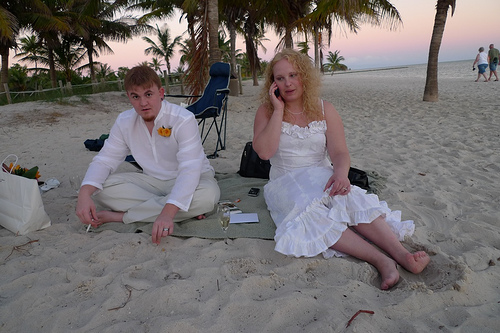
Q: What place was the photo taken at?
A: It was taken at the beach.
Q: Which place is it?
A: It is a beach.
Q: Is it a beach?
A: Yes, it is a beach.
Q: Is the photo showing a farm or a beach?
A: It is showing a beach.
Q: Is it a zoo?
A: No, it is a beach.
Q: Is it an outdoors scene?
A: Yes, it is outdoors.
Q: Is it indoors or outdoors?
A: It is outdoors.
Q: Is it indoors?
A: No, it is outdoors.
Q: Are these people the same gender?
A: No, they are both male and female.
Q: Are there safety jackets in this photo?
A: No, there are no safety jackets.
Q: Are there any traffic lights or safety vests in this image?
A: No, there are no safety vests or traffic lights.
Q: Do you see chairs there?
A: Yes, there is a chair.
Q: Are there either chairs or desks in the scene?
A: Yes, there is a chair.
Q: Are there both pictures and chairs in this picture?
A: No, there is a chair but no pictures.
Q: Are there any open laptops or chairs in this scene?
A: Yes, there is an open chair.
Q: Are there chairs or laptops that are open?
A: Yes, the chair is open.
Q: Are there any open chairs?
A: Yes, there is an open chair.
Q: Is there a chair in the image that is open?
A: Yes, there is a chair that is open.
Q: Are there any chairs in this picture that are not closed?
A: Yes, there is a open chair.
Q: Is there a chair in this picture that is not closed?
A: Yes, there is a open chair.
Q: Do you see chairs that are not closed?
A: Yes, there is a open chair.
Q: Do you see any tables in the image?
A: No, there are no tables.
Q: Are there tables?
A: No, there are no tables.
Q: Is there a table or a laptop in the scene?
A: No, there are no tables or laptops.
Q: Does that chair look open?
A: Yes, the chair is open.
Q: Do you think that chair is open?
A: Yes, the chair is open.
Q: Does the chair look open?
A: Yes, the chair is open.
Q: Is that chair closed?
A: No, the chair is open.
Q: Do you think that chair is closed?
A: No, the chair is open.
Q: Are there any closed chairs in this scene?
A: No, there is a chair but it is open.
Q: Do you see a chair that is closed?
A: No, there is a chair but it is open.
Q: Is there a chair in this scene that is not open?
A: No, there is a chair but it is open.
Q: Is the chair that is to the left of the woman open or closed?
A: The chair is open.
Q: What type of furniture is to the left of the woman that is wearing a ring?
A: The piece of furniture is a chair.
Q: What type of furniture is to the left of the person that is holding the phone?
A: The piece of furniture is a chair.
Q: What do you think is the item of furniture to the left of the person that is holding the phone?
A: The piece of furniture is a chair.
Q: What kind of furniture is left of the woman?
A: The piece of furniture is a chair.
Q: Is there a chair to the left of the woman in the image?
A: Yes, there is a chair to the left of the woman.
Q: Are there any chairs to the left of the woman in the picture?
A: Yes, there is a chair to the left of the woman.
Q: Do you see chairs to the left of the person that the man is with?
A: Yes, there is a chair to the left of the woman.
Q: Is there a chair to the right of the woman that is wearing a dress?
A: No, the chair is to the left of the woman.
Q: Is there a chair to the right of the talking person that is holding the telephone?
A: No, the chair is to the left of the woman.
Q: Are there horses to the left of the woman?
A: No, there is a chair to the left of the woman.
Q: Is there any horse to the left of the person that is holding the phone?
A: No, there is a chair to the left of the woman.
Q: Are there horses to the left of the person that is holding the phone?
A: No, there is a chair to the left of the woman.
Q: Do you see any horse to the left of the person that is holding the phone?
A: No, there is a chair to the left of the woman.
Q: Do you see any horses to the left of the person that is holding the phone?
A: No, there is a chair to the left of the woman.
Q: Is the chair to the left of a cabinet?
A: No, the chair is to the left of a woman.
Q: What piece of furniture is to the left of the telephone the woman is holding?
A: The piece of furniture is a chair.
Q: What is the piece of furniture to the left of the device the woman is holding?
A: The piece of furniture is a chair.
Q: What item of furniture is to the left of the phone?
A: The piece of furniture is a chair.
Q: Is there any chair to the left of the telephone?
A: Yes, there is a chair to the left of the telephone.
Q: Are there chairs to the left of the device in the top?
A: Yes, there is a chair to the left of the telephone.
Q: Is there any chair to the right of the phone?
A: No, the chair is to the left of the phone.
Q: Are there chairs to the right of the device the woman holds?
A: No, the chair is to the left of the phone.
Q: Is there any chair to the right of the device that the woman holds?
A: No, the chair is to the left of the phone.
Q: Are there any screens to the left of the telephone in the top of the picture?
A: No, there is a chair to the left of the phone.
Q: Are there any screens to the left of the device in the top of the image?
A: No, there is a chair to the left of the phone.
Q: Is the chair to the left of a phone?
A: Yes, the chair is to the left of a phone.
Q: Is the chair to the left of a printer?
A: No, the chair is to the left of a phone.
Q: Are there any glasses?
A: No, there are no glasses.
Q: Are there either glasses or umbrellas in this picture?
A: No, there are no glasses or umbrellas.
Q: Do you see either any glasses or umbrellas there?
A: No, there are no glasses or umbrellas.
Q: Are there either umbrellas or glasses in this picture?
A: No, there are no glasses or umbrellas.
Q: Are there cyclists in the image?
A: No, there are no cyclists.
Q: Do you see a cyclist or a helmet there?
A: No, there are no cyclists or helmets.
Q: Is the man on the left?
A: Yes, the man is on the left of the image.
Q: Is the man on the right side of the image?
A: No, the man is on the left of the image.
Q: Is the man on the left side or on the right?
A: The man is on the left of the image.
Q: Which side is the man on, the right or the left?
A: The man is on the left of the image.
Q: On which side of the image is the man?
A: The man is on the left of the image.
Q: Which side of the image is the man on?
A: The man is on the left of the image.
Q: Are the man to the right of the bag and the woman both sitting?
A: Yes, both the man and the woman are sitting.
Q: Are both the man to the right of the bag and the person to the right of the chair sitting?
A: Yes, both the man and the woman are sitting.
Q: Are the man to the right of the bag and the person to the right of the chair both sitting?
A: Yes, both the man and the woman are sitting.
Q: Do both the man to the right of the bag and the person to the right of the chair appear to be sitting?
A: Yes, both the man and the woman are sitting.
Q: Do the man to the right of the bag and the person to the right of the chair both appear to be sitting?
A: Yes, both the man and the woman are sitting.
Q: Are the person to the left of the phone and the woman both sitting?
A: Yes, both the man and the woman are sitting.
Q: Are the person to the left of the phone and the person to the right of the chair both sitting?
A: Yes, both the man and the woman are sitting.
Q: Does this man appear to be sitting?
A: Yes, the man is sitting.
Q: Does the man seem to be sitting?
A: Yes, the man is sitting.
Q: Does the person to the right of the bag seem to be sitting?
A: Yes, the man is sitting.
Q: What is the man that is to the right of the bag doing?
A: The man is sitting.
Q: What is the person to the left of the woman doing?
A: The man is sitting.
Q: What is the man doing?
A: The man is sitting.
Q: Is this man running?
A: No, the man is sitting.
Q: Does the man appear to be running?
A: No, the man is sitting.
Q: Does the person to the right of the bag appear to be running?
A: No, the man is sitting.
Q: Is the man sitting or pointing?
A: The man is sitting.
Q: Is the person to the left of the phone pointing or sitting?
A: The man is sitting.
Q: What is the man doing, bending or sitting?
A: The man is sitting.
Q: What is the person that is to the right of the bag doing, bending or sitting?
A: The man is sitting.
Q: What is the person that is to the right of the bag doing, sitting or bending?
A: The man is sitting.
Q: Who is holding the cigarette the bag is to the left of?
A: The man is holding the cigarette.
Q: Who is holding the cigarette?
A: The man is holding the cigarette.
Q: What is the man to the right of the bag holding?
A: The man is holding the cigarette.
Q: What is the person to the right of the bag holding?
A: The man is holding the cigarette.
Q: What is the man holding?
A: The man is holding the cigarette.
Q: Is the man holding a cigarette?
A: Yes, the man is holding a cigarette.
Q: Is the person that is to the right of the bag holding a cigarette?
A: Yes, the man is holding a cigarette.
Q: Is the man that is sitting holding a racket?
A: No, the man is holding a cigarette.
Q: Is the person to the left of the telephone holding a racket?
A: No, the man is holding a cigarette.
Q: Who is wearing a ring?
A: The man is wearing a ring.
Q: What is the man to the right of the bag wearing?
A: The man is wearing a ring.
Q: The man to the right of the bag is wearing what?
A: The man is wearing a ring.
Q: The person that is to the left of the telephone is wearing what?
A: The man is wearing a ring.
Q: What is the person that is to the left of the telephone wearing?
A: The man is wearing a ring.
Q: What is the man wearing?
A: The man is wearing a ring.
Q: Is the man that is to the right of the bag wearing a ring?
A: Yes, the man is wearing a ring.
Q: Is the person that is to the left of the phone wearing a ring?
A: Yes, the man is wearing a ring.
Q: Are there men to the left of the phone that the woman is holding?
A: Yes, there is a man to the left of the phone.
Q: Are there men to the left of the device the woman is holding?
A: Yes, there is a man to the left of the phone.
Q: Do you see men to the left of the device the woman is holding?
A: Yes, there is a man to the left of the phone.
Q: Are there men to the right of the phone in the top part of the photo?
A: No, the man is to the left of the telephone.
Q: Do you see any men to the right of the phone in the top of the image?
A: No, the man is to the left of the telephone.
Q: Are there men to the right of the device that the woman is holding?
A: No, the man is to the left of the telephone.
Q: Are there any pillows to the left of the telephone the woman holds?
A: No, there is a man to the left of the phone.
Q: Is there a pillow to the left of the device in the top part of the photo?
A: No, there is a man to the left of the phone.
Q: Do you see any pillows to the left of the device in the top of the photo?
A: No, there is a man to the left of the phone.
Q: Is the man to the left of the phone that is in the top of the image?
A: Yes, the man is to the left of the phone.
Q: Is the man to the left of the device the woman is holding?
A: Yes, the man is to the left of the phone.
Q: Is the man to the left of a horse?
A: No, the man is to the left of the phone.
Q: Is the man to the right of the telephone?
A: No, the man is to the left of the telephone.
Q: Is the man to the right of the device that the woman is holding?
A: No, the man is to the left of the telephone.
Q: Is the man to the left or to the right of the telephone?
A: The man is to the left of the telephone.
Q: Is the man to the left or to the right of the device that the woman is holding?
A: The man is to the left of the telephone.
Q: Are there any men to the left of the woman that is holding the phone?
A: Yes, there is a man to the left of the woman.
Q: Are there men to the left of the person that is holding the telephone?
A: Yes, there is a man to the left of the woman.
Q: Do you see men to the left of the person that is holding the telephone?
A: Yes, there is a man to the left of the woman.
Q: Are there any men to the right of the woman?
A: No, the man is to the left of the woman.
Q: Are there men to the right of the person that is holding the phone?
A: No, the man is to the left of the woman.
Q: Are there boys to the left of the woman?
A: No, there is a man to the left of the woman.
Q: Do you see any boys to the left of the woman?
A: No, there is a man to the left of the woman.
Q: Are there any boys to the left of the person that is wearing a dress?
A: No, there is a man to the left of the woman.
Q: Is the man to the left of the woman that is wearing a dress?
A: Yes, the man is to the left of the woman.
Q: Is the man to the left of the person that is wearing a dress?
A: Yes, the man is to the left of the woman.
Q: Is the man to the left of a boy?
A: No, the man is to the left of the woman.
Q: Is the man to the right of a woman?
A: No, the man is to the left of a woman.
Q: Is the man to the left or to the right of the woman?
A: The man is to the left of the woman.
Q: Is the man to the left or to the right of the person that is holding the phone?
A: The man is to the left of the woman.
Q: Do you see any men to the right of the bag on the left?
A: Yes, there is a man to the right of the bag.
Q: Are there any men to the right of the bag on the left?
A: Yes, there is a man to the right of the bag.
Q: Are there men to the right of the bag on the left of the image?
A: Yes, there is a man to the right of the bag.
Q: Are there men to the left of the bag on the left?
A: No, the man is to the right of the bag.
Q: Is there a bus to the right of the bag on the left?
A: No, there is a man to the right of the bag.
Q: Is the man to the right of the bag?
A: Yes, the man is to the right of the bag.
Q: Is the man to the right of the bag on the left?
A: Yes, the man is to the right of the bag.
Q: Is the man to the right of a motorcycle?
A: No, the man is to the right of the bag.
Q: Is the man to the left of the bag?
A: No, the man is to the right of the bag.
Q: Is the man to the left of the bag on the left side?
A: No, the man is to the right of the bag.